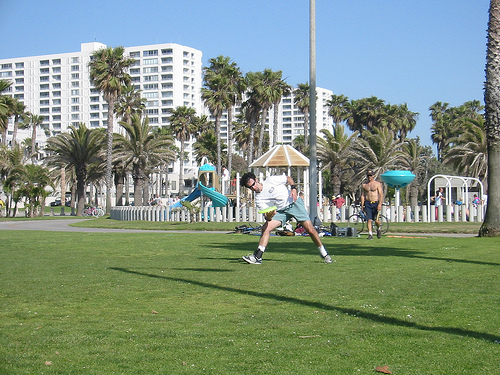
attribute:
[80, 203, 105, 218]
bicycle — leaning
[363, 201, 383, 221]
shorts — blue, man's shorts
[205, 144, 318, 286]
man — wearing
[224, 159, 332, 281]
man — wearing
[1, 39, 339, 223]
white buildings — tall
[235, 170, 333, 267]
man — wearing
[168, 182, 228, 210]
board — sliding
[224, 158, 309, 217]
man — wearing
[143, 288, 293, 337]
grass — short, green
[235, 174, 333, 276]
man — wearing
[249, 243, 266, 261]
ankle brace — black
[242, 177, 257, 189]
sunglasses — black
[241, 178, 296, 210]
shirt — white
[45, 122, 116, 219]
tree — palm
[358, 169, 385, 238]
shirtless man — walking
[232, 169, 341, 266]
man — wearing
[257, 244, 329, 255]
socks — white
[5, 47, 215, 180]
building — tall, white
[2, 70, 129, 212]
trees — green, many, palm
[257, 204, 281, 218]
frisbee — caught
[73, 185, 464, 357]
grass — green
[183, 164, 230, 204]
slides — blue, colored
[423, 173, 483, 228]
swingset — white